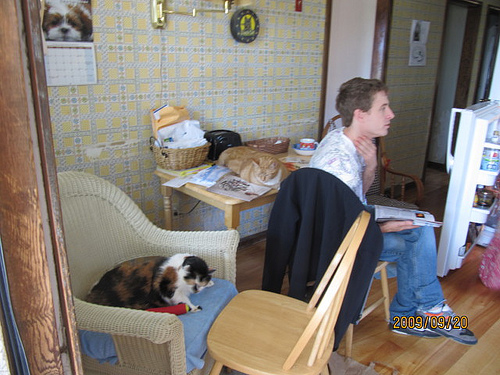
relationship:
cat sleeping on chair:
[77, 252, 216, 316] [46, 163, 237, 373]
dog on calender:
[38, 2, 95, 42] [26, 0, 96, 91]